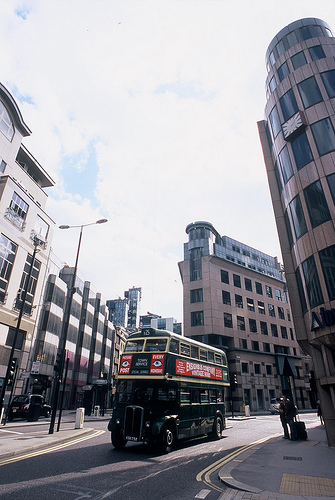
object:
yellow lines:
[195, 438, 283, 488]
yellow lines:
[1, 426, 105, 467]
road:
[0, 408, 332, 498]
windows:
[284, 42, 329, 72]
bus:
[106, 313, 232, 455]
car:
[5, 391, 51, 421]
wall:
[275, 144, 305, 281]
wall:
[32, 275, 119, 401]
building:
[255, 17, 333, 447]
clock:
[280, 110, 307, 141]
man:
[276, 392, 298, 438]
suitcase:
[288, 412, 308, 441]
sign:
[173, 355, 225, 380]